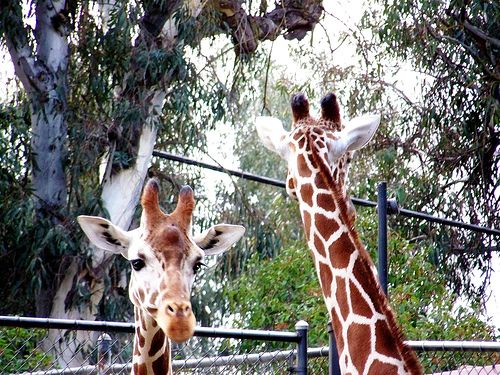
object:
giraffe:
[253, 91, 424, 375]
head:
[252, 91, 379, 199]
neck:
[291, 178, 420, 375]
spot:
[331, 235, 355, 267]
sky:
[0, 0, 499, 341]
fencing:
[0, 314, 306, 375]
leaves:
[176, 106, 185, 115]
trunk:
[37, 0, 206, 375]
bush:
[215, 206, 500, 373]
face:
[128, 224, 206, 340]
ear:
[344, 113, 380, 154]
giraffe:
[74, 178, 246, 375]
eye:
[129, 257, 148, 270]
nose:
[168, 300, 190, 316]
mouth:
[158, 321, 191, 344]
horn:
[317, 92, 340, 125]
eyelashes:
[195, 260, 209, 268]